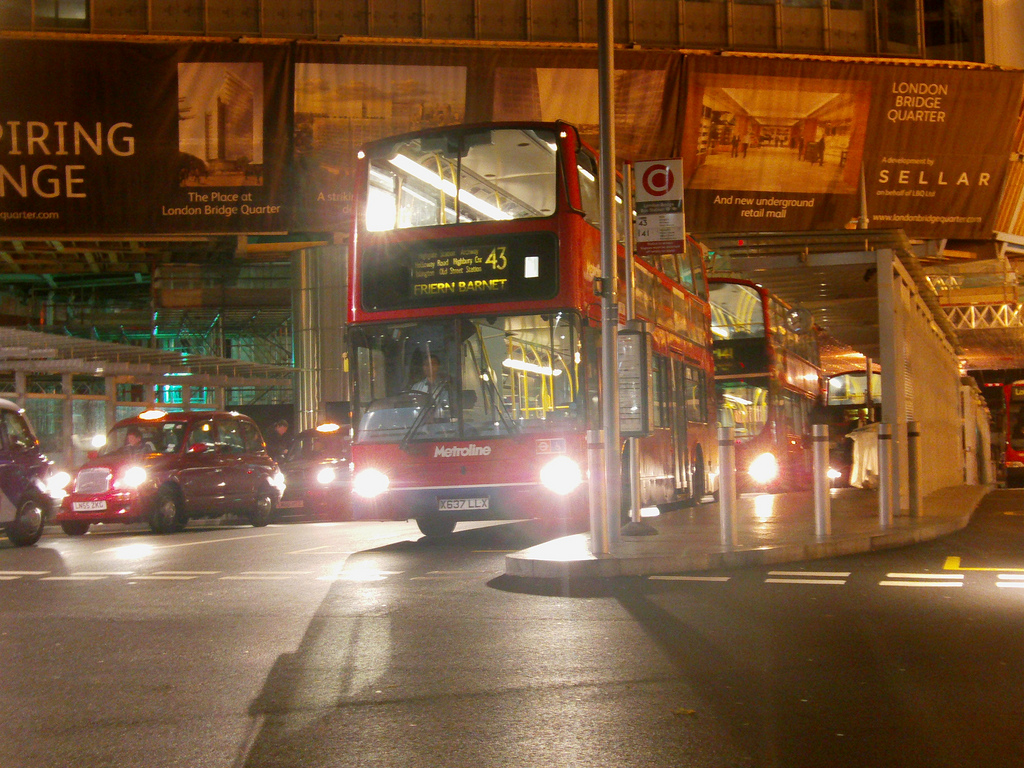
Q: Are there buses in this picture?
A: Yes, there is a bus.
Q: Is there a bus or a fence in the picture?
A: Yes, there is a bus.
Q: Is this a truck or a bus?
A: This is a bus.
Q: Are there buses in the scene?
A: Yes, there is a bus.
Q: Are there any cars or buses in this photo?
A: Yes, there is a bus.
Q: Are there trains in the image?
A: No, there are no trains.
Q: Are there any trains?
A: No, there are no trains.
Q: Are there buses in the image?
A: Yes, there is a bus.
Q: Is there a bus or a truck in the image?
A: Yes, there is a bus.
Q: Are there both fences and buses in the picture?
A: No, there is a bus but no fences.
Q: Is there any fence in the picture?
A: No, there are no fences.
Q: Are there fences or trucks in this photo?
A: No, there are no fences or trucks.